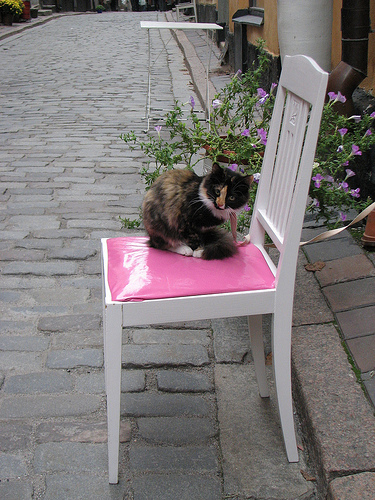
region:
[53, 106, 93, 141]
part of a walkpath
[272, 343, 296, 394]
stand of a chair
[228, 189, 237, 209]
eye of a cat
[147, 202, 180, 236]
stomach of a cat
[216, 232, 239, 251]
tail of a cat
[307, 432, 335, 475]
edge of a road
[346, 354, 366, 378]
part of a grass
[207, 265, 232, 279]
part of a chair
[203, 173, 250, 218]
face of a cat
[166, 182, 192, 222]
back of a cat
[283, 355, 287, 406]
back leg of a chair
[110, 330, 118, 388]
front leg of a chair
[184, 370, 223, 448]
section of a road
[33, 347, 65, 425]
part of a path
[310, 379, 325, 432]
edge of a pavement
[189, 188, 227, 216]
a cat on a chair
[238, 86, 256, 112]
section of a flower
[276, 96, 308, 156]
back rest of a chair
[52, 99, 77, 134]
portion of a road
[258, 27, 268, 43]
part of a wall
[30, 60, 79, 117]
part of a walkpath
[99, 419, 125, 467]
stand of a chair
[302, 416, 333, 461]
edge of a road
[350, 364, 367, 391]
part of a grass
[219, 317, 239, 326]
edge of a chair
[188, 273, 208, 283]
part of a chair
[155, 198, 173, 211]
part of a cat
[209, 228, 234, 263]
tail of a cat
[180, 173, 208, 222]
whiskers of a cat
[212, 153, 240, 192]
head of a cat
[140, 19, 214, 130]
White tray table on cobblestones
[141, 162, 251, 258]
Calico cat on chair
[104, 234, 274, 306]
Shiny pink chair cushion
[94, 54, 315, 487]
White wooden chair on cobblestones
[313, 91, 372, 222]
Purple flowers on bush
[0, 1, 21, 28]
Pot of yellow flowers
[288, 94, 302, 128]
Carved design on wooden chair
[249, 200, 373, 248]
White shoelace tied to chair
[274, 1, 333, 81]
Fat white pillar on wall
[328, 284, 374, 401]
Green grass growing in cracks of stone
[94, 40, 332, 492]
a cat on a chair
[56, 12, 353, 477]
the chair is pink and white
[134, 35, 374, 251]
the bush has purple flowers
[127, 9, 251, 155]
the table is white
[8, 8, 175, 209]
the road is made of brick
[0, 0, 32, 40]
a pot of yellow flowers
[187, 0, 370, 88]
the building is yellow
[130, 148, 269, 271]
a tabby cat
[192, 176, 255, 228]
the cat has wiskers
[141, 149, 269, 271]
the cat has a fluffy tail